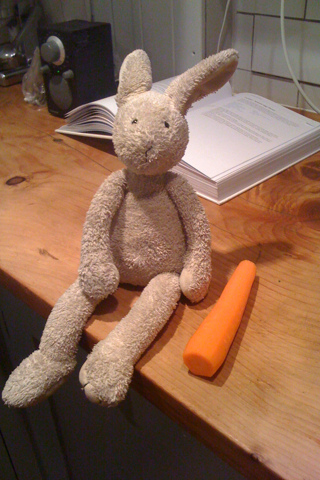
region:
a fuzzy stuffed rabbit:
[1, 44, 241, 412]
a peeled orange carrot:
[181, 258, 258, 376]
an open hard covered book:
[52, 69, 318, 205]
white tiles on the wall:
[225, 2, 319, 110]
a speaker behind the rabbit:
[34, 16, 115, 121]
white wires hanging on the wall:
[214, 0, 318, 112]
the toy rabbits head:
[107, 45, 243, 176]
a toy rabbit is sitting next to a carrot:
[2, 46, 257, 408]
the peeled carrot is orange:
[178, 256, 260, 378]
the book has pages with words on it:
[51, 60, 317, 204]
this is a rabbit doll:
[79, 76, 205, 307]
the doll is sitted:
[77, 87, 201, 294]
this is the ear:
[166, 42, 241, 102]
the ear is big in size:
[167, 42, 244, 107]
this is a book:
[221, 102, 301, 167]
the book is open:
[203, 95, 283, 170]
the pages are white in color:
[220, 104, 288, 175]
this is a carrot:
[187, 263, 263, 387]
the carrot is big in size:
[197, 258, 267, 372]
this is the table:
[261, 375, 309, 452]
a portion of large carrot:
[202, 284, 236, 368]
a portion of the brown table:
[257, 335, 307, 430]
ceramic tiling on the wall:
[252, 11, 279, 80]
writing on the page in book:
[212, 99, 282, 145]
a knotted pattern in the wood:
[5, 171, 49, 192]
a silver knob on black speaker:
[36, 30, 62, 61]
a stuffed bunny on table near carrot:
[5, 42, 238, 410]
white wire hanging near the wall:
[281, 3, 305, 93]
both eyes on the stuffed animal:
[129, 116, 169, 127]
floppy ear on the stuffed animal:
[118, 58, 149, 92]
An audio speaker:
[36, 18, 116, 119]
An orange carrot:
[181, 259, 257, 379]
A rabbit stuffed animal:
[0, 45, 239, 408]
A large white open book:
[55, 61, 318, 203]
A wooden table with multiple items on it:
[0, 42, 317, 478]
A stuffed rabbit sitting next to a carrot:
[0, 49, 260, 410]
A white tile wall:
[234, 0, 318, 113]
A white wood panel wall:
[46, 0, 205, 86]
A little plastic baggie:
[18, 45, 47, 110]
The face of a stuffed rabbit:
[114, 96, 183, 175]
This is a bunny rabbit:
[77, 40, 181, 429]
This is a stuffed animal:
[0, 43, 190, 409]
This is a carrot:
[191, 237, 233, 471]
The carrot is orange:
[215, 253, 257, 393]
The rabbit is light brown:
[67, 164, 174, 393]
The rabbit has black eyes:
[83, 100, 189, 163]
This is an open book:
[215, 42, 319, 171]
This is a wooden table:
[196, 391, 312, 419]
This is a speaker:
[39, 57, 111, 106]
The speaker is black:
[34, 52, 111, 142]